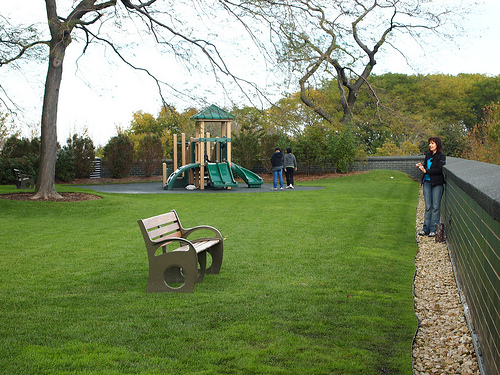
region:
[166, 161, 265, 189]
the slides are green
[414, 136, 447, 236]
a woman is standing by the wall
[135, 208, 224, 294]
the bench is empty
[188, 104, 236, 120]
the top of the playground is green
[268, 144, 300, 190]
two people are standing by the playground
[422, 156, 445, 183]
a woman is wearing a blue shirt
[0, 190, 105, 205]
there is gravel around the base of the tree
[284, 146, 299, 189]
a woman is wearing white shoes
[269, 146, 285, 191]
a man is wearing blue jeans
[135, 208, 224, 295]
the bench is brown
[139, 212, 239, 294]
A bench in the park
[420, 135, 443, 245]
There is a woman standing and smiling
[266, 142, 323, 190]
Two people are walking together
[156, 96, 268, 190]
There is a play house with gliding and climbing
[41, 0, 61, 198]
The balk of a tall tree in the park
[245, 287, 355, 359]
The grass of this park is flush green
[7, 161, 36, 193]
Another bench on the other side of this park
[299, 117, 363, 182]
Part of a line of trees by the fence wall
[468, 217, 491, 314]
The fence wall is of bricks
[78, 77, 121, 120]
It is a clear day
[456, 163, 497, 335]
black and green wall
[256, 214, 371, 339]
well-trimmed green grass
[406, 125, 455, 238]
woman standing next to wall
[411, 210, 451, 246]
bag at woman's feet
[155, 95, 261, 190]
children's play area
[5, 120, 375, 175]
bushes near wall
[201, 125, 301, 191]
people standing near play area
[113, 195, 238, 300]
bench on grass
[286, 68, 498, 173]
trees behind wall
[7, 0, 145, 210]
large tree set in circular clearing in grass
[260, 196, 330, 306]
the grass is very green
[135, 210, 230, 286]
the bench is grey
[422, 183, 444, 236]
the jeans are green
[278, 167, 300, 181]
the pants are black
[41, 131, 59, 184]
the tree trunk is grey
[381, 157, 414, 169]
the wall is made of bricks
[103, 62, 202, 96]
the sky is cloudy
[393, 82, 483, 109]
the trees are green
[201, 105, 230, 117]
the roof is green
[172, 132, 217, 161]
the wooden poles are brown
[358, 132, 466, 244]
a woman by a fence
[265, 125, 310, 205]
a couple taking a walk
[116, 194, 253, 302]
an empty park bench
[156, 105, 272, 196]
a slide set for children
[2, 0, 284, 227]
a tree beginning to bud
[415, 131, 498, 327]
a lady against a brick wall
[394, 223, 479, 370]
a gravel border by the fence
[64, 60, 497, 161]
deciduous trees in the background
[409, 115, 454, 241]
a lady in a black jacket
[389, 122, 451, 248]
a woman standing by her bag